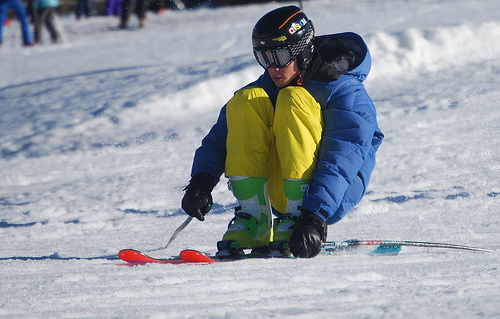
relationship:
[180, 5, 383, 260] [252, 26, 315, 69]
man wearing glasses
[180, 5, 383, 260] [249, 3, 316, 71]
man wearing helmet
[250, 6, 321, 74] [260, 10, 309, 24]
helment with stripe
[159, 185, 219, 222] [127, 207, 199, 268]
hand holding pole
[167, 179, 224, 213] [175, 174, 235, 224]
glove on hand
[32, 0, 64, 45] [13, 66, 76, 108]
man walking on snow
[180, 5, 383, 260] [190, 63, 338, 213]
man wearing jacket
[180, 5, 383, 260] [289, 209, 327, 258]
man wearing glove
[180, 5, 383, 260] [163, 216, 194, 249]
man holding pole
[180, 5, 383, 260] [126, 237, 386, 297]
man on board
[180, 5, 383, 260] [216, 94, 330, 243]
man wearing pants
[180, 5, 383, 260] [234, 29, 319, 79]
man wearing glasses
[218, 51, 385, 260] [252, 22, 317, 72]
man wearing helment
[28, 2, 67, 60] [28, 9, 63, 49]
man wearing pants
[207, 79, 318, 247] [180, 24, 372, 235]
pants on girl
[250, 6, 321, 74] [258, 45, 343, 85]
helment on head